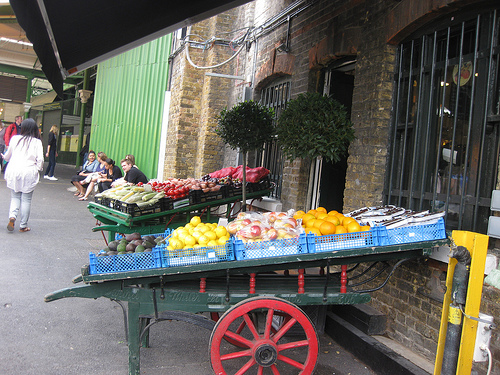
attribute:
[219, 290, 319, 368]
wheel — red, close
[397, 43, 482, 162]
bars — black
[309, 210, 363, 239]
oranges — visable, alone, big, orange, close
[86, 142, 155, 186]
people — close, together, looking, sitting, talking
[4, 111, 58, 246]
girl — close, skinny, walking, here, standing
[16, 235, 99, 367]
street — busy, white, grey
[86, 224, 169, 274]
basket — blue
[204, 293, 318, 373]
wheel — red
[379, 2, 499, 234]
bars — black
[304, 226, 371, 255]
crate — blue